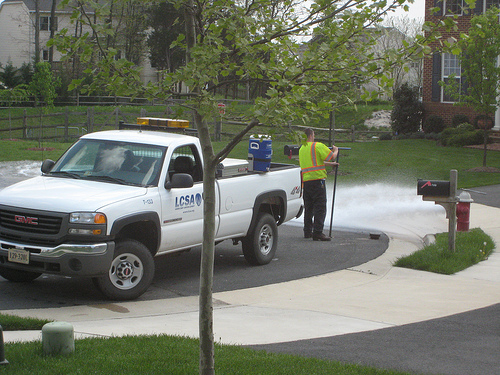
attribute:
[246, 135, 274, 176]
cooler — blue, cylindrical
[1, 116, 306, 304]
truck — white, gmc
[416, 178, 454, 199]
mailbox — black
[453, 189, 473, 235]
hydrant — red, white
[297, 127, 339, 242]
man — utility worker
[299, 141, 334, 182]
shirt — yellow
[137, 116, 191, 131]
lights — orange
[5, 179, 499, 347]
sidewalk — concrete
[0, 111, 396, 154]
fence — wooden, brown, split rail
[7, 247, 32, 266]
plate — white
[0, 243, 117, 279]
bumper — gray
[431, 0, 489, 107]
shutters — black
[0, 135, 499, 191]
yard — maintained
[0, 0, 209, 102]
building — tan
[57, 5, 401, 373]
tree — slim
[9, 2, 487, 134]
leaves — green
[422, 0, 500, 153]
house — brick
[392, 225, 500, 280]
grass — green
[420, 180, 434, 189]
flag — red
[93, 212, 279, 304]
wheels — black